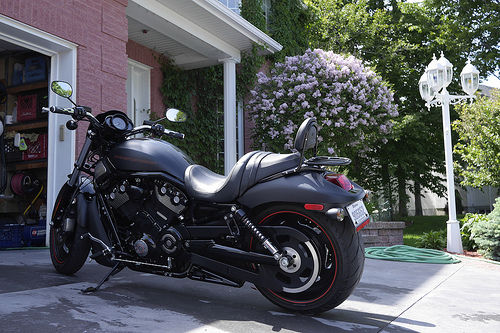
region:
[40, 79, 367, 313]
a black motorcycle in a driveway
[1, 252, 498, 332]
a concrete driveway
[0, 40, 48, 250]
a garage with open door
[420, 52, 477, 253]
a white lamppost with for lamps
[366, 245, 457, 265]
a green garden hose on driveway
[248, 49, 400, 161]
a purple lilac bush behind motorcycle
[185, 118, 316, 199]
the motorcycle's black leather seat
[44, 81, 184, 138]
the motorcycle's handlebars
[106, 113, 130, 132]
gauges on the motorcycle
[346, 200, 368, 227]
the bike's back license plate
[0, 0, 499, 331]
A house with a motorcycle in the driveway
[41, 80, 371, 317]
A black motorcycle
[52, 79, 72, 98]
A mirror on a motorcycle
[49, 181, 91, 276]
A front tire on a motorcycle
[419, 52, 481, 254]
white lights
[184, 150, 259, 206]
A seat on a motorcycle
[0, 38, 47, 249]
A garage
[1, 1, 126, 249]
A garage with red wall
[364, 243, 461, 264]
A green hose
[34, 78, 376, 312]
a motorcycle sitting in the driveway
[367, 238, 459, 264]
the hose sitting in the driveway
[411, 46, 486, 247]
the lights sitting on top of a pole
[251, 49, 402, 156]
the plant with white flowers on it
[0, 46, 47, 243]
the open garage door of the house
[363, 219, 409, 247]
the brick wall next to the plant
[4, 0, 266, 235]
the house the motorcycle is parked at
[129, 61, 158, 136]
the front door of the house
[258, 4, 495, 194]
some green leafy trees in front of the house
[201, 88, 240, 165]
a window in front of the house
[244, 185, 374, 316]
part of black motorcycle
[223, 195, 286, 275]
part of black motorcycle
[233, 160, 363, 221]
part of black motorcycle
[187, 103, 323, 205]
part of black motorcycle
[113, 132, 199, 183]
part of black motorcycle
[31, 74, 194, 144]
part of black motorcycle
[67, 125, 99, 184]
part of black motorcycle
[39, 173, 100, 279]
part of black motorcycle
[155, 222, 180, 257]
part of black motorcycle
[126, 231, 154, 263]
part of black motorcycle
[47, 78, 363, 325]
black motorcycle in the driveway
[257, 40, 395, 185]
bush with white flowers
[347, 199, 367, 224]
license plate on back of motorcycle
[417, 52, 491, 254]
white lamp post with four lights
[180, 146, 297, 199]
black seat on the motorcycle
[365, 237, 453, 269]
green hose pipe on the driveway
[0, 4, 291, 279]
house behind the motorcycle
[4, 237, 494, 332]
water stains on the driveway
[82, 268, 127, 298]
black kickstand on the motorcycle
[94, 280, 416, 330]
shadow of the motorcycle on driveway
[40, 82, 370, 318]
a motorcycle in a driveway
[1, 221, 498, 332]
a wet driveway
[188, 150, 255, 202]
leather motorcycle seat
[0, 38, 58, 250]
an open garage door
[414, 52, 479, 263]
an outdoor lamp in a yard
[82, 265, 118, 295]
a motorcycle kick stand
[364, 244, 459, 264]
a coiled water hose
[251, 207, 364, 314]
a tire on a motorcycle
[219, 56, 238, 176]
a white column on a porch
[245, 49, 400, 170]
a small flowering tree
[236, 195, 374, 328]
rear wheel of a motorcycle